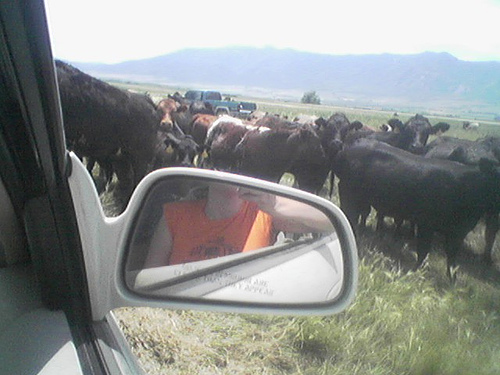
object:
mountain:
[110, 43, 498, 97]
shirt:
[165, 197, 269, 262]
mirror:
[124, 177, 351, 309]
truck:
[1, 0, 362, 373]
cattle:
[48, 57, 200, 207]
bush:
[298, 90, 319, 107]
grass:
[125, 239, 498, 372]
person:
[143, 178, 332, 273]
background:
[51, 0, 499, 122]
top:
[134, 164, 337, 212]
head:
[288, 122, 327, 166]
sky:
[44, 1, 499, 117]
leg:
[339, 178, 359, 232]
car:
[3, 1, 355, 372]